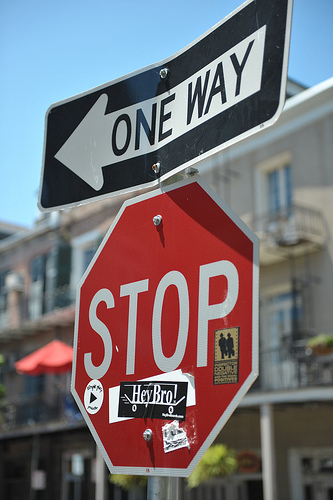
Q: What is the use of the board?
A: Direction.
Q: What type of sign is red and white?
A: A stop sign.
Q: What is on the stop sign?
A: Stickers.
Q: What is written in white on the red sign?
A: Stop.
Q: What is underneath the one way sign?
A: A stop sign.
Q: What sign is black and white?
A: One way sign.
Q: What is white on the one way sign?
A: An arrow.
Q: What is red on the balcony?
A: An umbrella.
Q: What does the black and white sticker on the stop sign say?
A: Hey bro.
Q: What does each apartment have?
A: A balcony.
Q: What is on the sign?
A: Lettering.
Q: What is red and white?
A: Stop sign.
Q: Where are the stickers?
A: On the stop sign.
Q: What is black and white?
A: The sign.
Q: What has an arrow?
A: Sign.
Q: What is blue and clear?
A: Sky.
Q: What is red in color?
A: Sign.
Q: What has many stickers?
A: Sign.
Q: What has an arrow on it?
A: Sign.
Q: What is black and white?
A: The sign.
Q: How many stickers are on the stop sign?
A: 5.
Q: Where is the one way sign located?
A: Above stop sign.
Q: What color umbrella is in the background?
A: Red.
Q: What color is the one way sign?
A: Black and white.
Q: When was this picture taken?
A: Daytime.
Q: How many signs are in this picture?
A: 2.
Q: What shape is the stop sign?
A: Octagon.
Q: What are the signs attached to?
A: Pole.